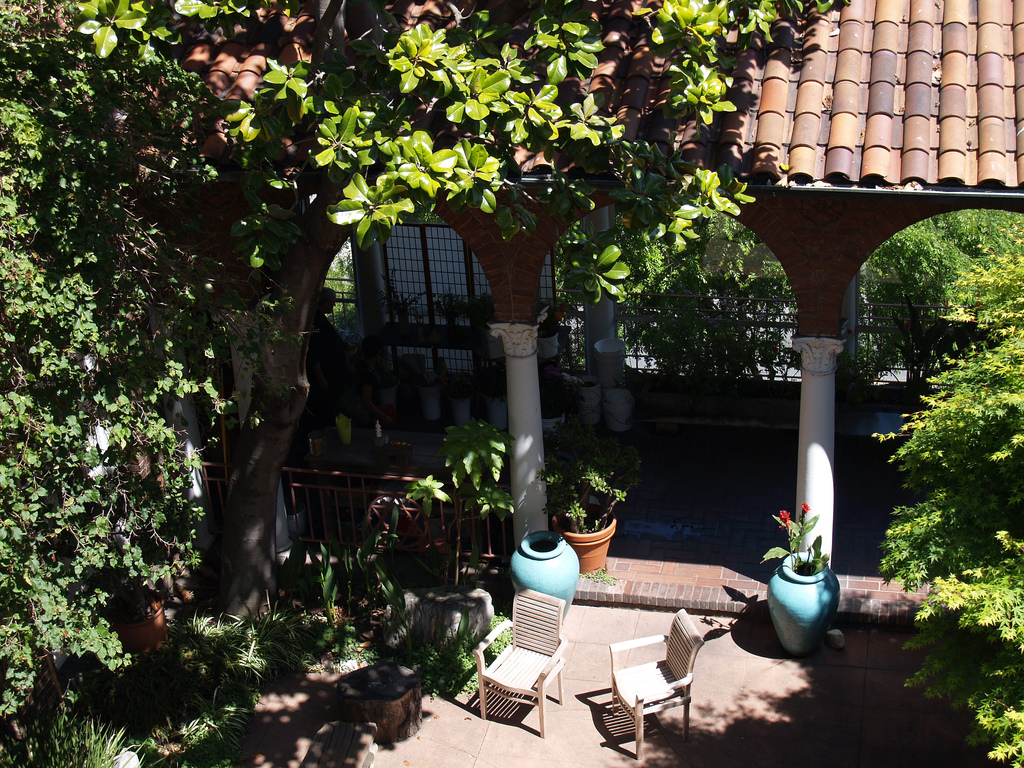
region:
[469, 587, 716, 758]
two white patio chairs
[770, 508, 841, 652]
flowers in a large teal planter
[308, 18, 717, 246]
green leaves on a tree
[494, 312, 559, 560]
a white support pillar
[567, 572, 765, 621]
a step up made from bricks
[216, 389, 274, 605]
the trunk of a tree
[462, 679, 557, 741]
a shadow being cast on the ground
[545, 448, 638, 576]
a shrub in a terracotta planter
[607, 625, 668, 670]
the white armrest of a chair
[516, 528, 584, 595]
the blue pot covered by the chair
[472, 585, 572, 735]
the chair is wooden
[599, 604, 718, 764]
the chair is angled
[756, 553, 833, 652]
the pot is blue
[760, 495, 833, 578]
the red flowers in the blue pot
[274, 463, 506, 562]
the red hand rail on the porch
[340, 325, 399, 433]
the woman on the porch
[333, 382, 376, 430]
the light brown purse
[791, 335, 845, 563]
the column behind the blue pot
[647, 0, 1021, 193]
the roof over the patio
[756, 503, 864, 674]
the blue vase with red flowers in it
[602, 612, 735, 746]
the chair facing off to the left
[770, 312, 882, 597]
the right white column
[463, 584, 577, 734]
the chair that is facing the front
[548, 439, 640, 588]
the tan pot with the green plant in it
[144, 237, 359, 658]
the visible tree trunk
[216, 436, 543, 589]
the red railing around the porch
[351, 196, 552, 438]
the white window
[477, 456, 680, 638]
pots on the ground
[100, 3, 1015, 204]
red colored roofing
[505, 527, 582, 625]
empty blue vase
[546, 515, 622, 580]
browish colored vase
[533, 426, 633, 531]
plant in a brownish vase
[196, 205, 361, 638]
grey colored tree trunk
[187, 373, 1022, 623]
area under a roof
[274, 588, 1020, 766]
uncovered area of a patio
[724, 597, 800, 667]
shadow of a blue vase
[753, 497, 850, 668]
a pot color blue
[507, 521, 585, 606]
the blue pot is empty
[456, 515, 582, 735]
a chair on front a pot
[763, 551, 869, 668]
blue vase on the pavement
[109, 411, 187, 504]
green and purple leaves on the trees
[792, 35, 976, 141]
Italian brown tile on top of roof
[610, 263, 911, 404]
fence at side of porch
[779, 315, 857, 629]
white column at base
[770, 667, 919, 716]
lines in the tiles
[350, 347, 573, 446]
small white flower pots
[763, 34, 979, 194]
a roof that is red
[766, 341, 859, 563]
a collumn that is white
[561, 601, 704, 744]
a chair that is white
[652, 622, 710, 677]
the back of a chair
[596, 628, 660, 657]
the right arm of a chair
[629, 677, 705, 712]
the left arm of a chair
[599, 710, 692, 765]
the legs on a chair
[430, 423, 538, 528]
some leaves that are green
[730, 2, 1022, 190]
surface of tile roof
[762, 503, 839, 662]
flowers in blue planter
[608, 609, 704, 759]
light on empty outdoor chair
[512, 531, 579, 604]
empty hole of blue planter